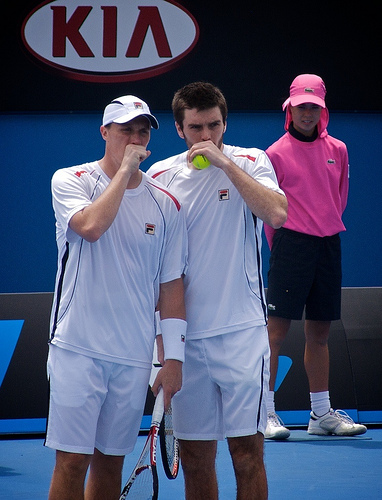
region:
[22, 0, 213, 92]
The logo says KIA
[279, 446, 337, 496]
The floor of the court is blue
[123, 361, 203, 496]
The men have tennis rackets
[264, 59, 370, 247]
The person in back is wearing pink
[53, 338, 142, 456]
The man has white shorts on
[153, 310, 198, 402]
The man has a band on his wrist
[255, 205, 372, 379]
The person in back has black shorts on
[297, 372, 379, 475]
The person has socks and shoes on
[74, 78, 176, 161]
The man has a hat on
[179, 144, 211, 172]
The person is holding the ball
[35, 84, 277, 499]
two men with their hands in front of their mouthss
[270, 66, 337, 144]
bright pink hat with side flaps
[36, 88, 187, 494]
man holding a tennis racket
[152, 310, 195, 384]
sweat band on man's wrist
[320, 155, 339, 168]
alligator logo on pink shirt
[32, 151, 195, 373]
white shirt with red and black trim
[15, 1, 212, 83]
car company logo in background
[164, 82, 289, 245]
man holding a tennis ball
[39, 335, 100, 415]
pocket showing through white shorts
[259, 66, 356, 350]
woman dressed to avoid sun exposure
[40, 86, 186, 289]
guy with fist to mouth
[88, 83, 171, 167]
guy wearing white cap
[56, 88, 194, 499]
guy holding tennis racquet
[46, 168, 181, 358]
black stripe on side of white shirt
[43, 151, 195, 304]
red stripes on white shoulders on shirt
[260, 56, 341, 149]
person with pink cap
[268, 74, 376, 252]
person wearing pink shirt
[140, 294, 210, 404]
white wristband on arm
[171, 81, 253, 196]
guy holding tennis ball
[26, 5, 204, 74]
red and white sign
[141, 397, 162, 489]
man holding tennis racquet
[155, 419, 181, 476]
man holding tennis racquet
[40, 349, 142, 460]
male tennis player wearing white shorts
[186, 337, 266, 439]
male tennis player wearing white shorts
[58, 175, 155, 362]
male tennis player wearing white shirt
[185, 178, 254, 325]
male tennis player wearing white shirt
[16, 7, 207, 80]
red and white sign on tennis court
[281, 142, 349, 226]
young woman wearing pink and black sweater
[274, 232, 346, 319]
woman wearing black shorts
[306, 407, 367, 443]
woman wearing white shoes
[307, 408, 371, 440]
a white tennis shoe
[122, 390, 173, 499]
a red, white and black tennis racket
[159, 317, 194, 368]
a white wrist band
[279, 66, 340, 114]
a pink ball cap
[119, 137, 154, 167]
a hand of a person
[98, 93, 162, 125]
a white and black ball cap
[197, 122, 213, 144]
a nose of a person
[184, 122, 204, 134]
an eye of a person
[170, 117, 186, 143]
an ear of a person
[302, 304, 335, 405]
a leg of a person